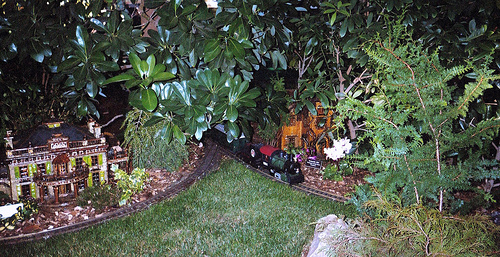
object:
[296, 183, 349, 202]
track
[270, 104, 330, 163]
no train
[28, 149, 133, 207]
balcony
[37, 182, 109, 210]
entrance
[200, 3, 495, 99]
tree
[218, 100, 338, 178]
train set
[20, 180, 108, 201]
columns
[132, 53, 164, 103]
leaves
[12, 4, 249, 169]
tree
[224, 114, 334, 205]
train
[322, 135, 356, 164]
white flower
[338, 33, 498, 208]
bush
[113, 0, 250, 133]
bush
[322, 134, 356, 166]
flower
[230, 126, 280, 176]
train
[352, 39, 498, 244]
tree leaves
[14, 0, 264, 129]
tree leaves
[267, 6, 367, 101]
tree leaves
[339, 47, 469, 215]
little tree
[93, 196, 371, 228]
ground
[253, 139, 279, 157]
red top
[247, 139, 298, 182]
train car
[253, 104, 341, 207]
train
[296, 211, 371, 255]
rock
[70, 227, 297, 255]
grass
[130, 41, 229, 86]
leaves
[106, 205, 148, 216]
train tracks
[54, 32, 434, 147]
branches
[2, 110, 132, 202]
building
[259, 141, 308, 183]
train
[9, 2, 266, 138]
tree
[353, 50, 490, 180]
tree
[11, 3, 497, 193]
trees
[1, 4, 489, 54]
leaves